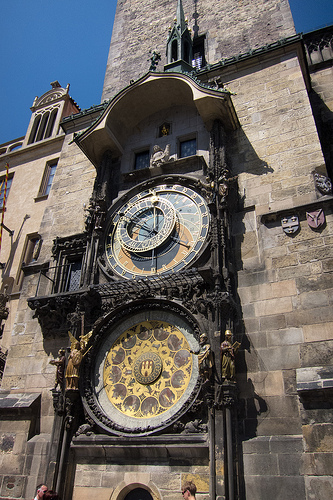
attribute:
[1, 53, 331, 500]
wall — stone, brick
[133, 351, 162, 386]
centerpiece — yellow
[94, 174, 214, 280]
clock — fancy, round, large, metal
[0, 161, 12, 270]
pole — red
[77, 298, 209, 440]
circle — yellow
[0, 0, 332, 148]
sky — blue, cloudless